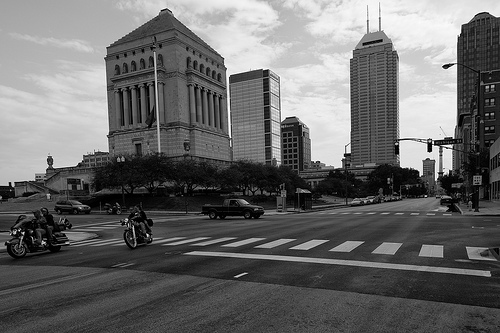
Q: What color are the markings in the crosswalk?
A: White.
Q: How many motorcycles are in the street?
A: 2.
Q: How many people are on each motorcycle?
A: 2.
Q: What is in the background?
A: Buildings.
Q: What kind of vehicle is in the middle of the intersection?
A: Truck.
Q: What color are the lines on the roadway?
A: White.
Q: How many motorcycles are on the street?
A: 2.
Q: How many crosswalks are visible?
A: 3.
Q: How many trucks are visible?
A: 1.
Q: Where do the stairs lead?
A: To an old building.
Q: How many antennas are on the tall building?
A: 2.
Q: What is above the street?
A: A traffic light.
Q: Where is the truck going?
A: Across the intersection.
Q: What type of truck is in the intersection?
A: A pickup truck.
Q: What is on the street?
A: Lines.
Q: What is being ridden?
A: Motorcycles.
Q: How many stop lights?
A: Two.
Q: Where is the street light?
A: Over the street.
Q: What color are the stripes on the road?
A: White.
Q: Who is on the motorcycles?
A: Bike riders.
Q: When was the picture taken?
A: Daytime.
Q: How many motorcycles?
A: 2.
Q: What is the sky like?
A: Overcast.